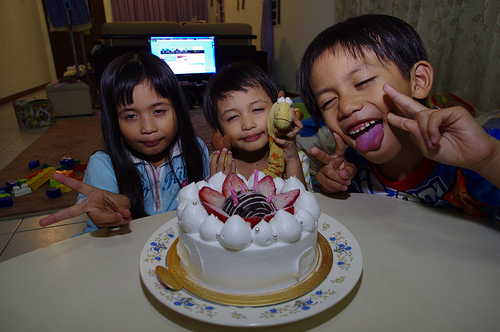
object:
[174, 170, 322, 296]
cake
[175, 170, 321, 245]
icing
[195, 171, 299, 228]
flower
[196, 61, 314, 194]
child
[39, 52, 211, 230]
girl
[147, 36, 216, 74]
screen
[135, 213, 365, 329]
dish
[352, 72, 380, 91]
eyes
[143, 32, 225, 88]
laptop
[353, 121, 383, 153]
tongue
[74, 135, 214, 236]
shirt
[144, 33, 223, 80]
television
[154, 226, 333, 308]
platter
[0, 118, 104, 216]
rug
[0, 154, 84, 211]
blocks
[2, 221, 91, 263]
tiles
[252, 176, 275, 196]
strawberry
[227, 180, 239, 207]
candle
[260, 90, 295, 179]
giraffe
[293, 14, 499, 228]
boy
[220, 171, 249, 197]
strawberries